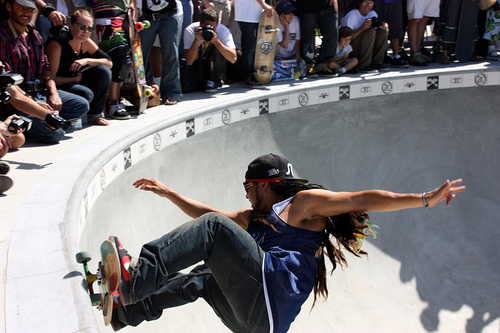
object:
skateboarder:
[78, 140, 465, 328]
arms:
[284, 176, 470, 220]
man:
[180, 5, 237, 92]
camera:
[196, 22, 215, 42]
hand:
[421, 177, 467, 207]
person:
[118, 149, 481, 331]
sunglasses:
[74, 20, 97, 33]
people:
[1, 1, 90, 141]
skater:
[103, 151, 465, 331]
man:
[68, 147, 465, 326]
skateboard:
[122, 1, 161, 120]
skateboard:
[252, 4, 281, 87]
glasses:
[242, 179, 264, 193]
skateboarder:
[109, 151, 466, 331]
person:
[231, 0, 280, 87]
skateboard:
[70, 236, 123, 328]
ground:
[414, 144, 472, 170]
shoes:
[105, 232, 147, 288]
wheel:
[71, 237, 123, 326]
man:
[141, 151, 386, 302]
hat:
[243, 139, 310, 186]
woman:
[40, 21, 138, 106]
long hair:
[259, 173, 376, 308]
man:
[137, 172, 349, 319]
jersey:
[246, 190, 327, 333]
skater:
[64, 148, 459, 327]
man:
[339, 0, 392, 71]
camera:
[368, 15, 381, 28]